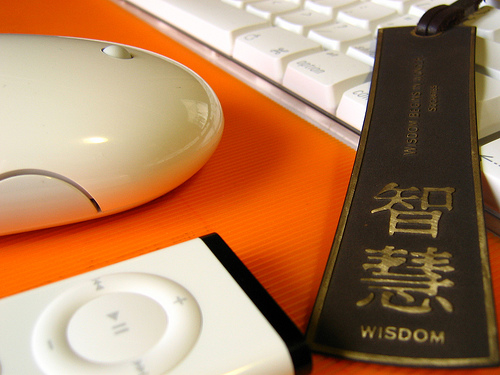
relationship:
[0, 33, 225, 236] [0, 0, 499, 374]
mouse on pad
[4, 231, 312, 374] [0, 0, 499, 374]
remote on pad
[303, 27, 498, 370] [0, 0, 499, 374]
bookmark on pad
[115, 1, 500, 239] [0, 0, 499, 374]
keyboard on pad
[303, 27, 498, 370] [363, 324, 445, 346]
bookmark says wisdom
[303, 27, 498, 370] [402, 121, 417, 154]
bookmark says wisdom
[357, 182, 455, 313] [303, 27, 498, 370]
character on bookmark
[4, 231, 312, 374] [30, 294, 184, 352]
remote has volume control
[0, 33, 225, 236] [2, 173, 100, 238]
mouse has button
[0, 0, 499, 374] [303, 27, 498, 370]
pad has bookmark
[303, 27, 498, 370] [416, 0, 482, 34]
bookmark has clip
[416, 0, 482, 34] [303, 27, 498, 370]
clip holds bookmark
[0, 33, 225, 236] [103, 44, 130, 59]
mouse has clicker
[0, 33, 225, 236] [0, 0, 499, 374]
mouse next to pad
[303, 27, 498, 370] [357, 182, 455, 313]
bookmark has character